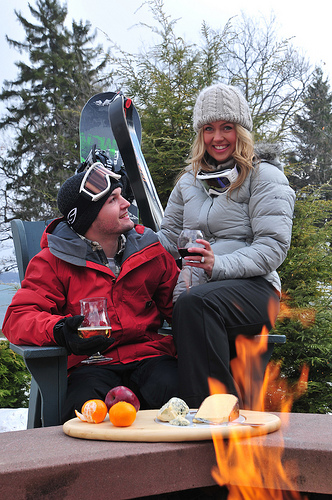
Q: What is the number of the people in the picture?
A: 2.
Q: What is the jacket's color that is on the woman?
A: Grey.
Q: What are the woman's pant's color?
A: Black.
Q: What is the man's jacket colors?
A: Red and grey.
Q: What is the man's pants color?
A: Black.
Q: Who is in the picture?
A: A man and a woman.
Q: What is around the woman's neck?
A: Goggles.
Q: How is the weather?
A: Clear.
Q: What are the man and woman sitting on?
A: Chair.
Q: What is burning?
A: A fire.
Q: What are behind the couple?
A: Skis.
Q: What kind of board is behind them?
A: Snowboard.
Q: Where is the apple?
A: On the food tray.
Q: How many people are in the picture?
A: Two.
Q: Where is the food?
A: By the firepit.